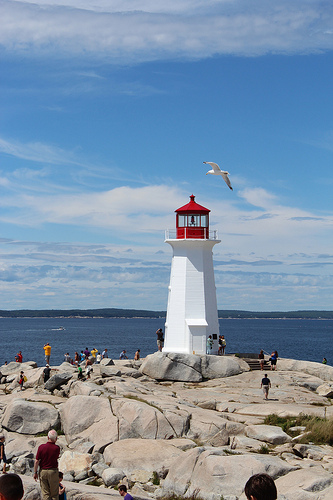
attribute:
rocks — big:
[119, 404, 231, 481]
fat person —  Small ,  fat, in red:
[14, 349, 26, 363]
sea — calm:
[0, 316, 331, 362]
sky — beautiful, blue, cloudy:
[0, 1, 332, 308]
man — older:
[32, 428, 61, 498]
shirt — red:
[35, 442, 61, 468]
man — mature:
[29, 426, 63, 498]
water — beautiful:
[2, 316, 332, 369]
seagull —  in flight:
[195, 129, 244, 202]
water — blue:
[240, 323, 313, 348]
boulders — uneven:
[1, 353, 332, 499]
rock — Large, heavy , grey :
[138, 351, 251, 383]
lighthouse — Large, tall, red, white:
[159, 191, 225, 357]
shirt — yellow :
[38, 342, 54, 357]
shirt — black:
[257, 378, 272, 388]